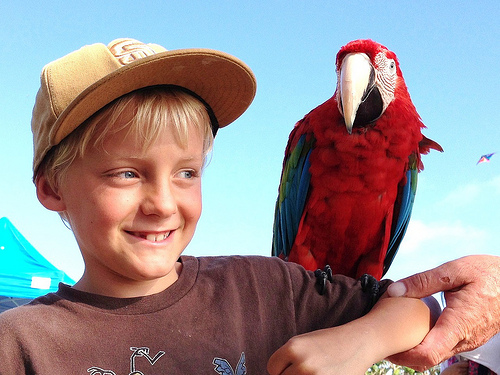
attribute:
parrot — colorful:
[271, 37, 445, 304]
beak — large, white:
[338, 51, 383, 135]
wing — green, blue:
[271, 117, 321, 258]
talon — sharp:
[320, 277, 327, 295]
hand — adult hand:
[382, 253, 499, 372]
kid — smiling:
[0, 37, 442, 375]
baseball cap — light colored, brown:
[29, 37, 259, 184]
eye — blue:
[173, 169, 192, 179]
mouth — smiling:
[121, 224, 182, 249]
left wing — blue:
[380, 148, 419, 278]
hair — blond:
[32, 84, 214, 230]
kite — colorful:
[476, 152, 497, 166]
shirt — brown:
[0, 255, 396, 375]